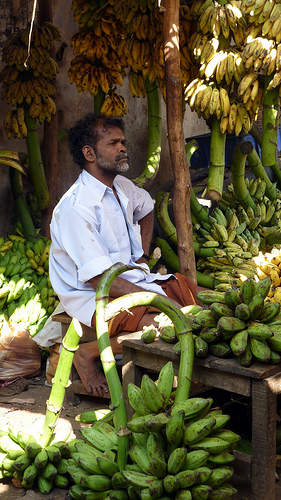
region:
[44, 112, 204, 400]
man in a white collared shirt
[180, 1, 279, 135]
several bunches of ripe bananas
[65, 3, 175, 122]
several bunches of over ripe bananas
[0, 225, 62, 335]
several bunches of green bananas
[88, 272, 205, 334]
shorts made of orange fabric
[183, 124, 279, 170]
blue plastic bucket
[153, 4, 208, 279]
skinny brown tree trunk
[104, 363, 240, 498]
bunches of green bananas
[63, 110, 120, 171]
curly black thinning hair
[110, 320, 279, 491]
worn wooden table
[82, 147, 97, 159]
the ear of a man seated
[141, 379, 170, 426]
a bunch of green bananas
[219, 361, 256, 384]
a wooden table holding bananas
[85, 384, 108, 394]
a man's toes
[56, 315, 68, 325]
a stool holding a man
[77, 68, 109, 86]
a bunch of ripe bananas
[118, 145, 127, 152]
the nose of a man seated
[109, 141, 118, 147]
the eye of a man seated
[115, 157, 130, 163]
the mouth of a man seated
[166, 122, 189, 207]
a pole in the middle of the stall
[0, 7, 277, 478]
a man in middle of bucnhes of banana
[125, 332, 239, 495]
a bunch of green bananas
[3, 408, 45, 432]
the sunlight reflected on the ground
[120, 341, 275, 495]
a rustic wooden table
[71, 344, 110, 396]
one foot of the man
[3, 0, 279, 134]
some bunches of banana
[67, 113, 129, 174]
the head of the man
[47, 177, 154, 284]
the long sleeves of the shirt rolled up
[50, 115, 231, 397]
this man is pensive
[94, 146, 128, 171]
the beard of the man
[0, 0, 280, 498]
a fruit market stall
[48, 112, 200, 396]
a man selling bananas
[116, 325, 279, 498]
a wooden table in the market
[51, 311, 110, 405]
the man's wooden stool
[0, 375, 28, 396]
one of the man's sandals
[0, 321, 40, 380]
a tan shopping bag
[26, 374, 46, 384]
one of the man's sandals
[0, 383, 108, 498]
an area of dirt ground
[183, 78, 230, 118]
a bunch of yellow bananas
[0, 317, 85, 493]
a bunch of green bananas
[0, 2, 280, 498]
man is selling bananas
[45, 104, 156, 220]
man has gray hair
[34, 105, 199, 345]
man wears a long sleeve shirt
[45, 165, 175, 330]
a white long sleeve shirt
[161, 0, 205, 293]
a pole of wood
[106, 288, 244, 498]
a handle of bananas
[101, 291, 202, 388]
stem of banana tree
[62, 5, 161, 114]
handles of riped bananas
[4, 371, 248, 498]
unripe bananas on a stem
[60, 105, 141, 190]
man has a goatee beard